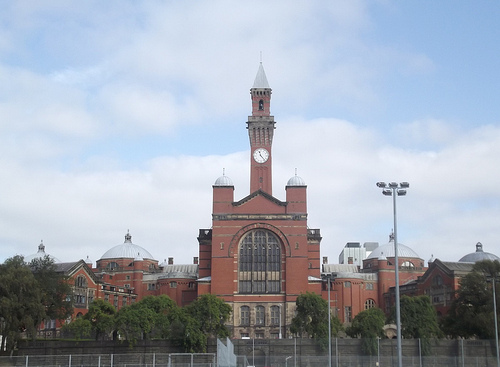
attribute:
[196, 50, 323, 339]
building — red, brick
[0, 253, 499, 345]
trees — green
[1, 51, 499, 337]
front — building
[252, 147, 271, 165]
clock — numbers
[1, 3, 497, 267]
sky — blue, cloudy, white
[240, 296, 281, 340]
windows — tall , parallel 